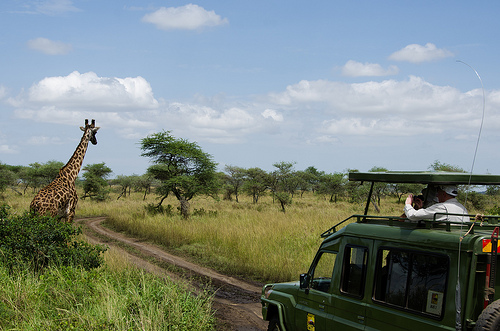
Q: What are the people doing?
A: Sightseeing.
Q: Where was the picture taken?
A: Jungle.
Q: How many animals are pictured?
A: 1.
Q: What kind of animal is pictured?
A: Giraffe.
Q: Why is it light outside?
A: Sunny.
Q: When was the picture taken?
A: Morning.